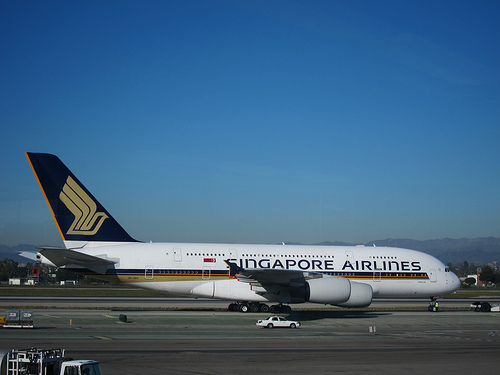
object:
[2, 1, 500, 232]
sky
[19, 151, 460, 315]
plane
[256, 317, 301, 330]
car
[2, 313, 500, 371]
runway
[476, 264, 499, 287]
tree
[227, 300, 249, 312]
wheels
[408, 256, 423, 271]
writing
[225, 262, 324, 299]
wing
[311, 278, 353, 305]
engines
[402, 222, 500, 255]
mountains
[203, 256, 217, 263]
sign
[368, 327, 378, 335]
object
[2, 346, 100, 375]
truck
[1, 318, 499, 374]
ground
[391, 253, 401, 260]
windows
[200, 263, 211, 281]
door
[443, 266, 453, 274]
cockpit windows